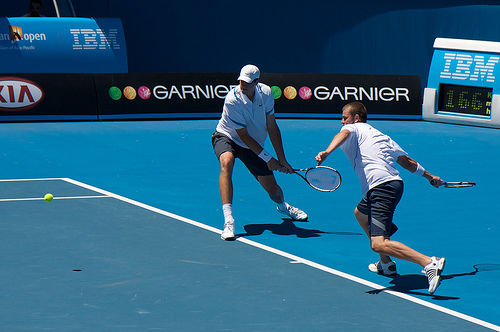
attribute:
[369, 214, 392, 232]
stripe — purple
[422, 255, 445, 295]
sneakers — white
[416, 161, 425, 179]
band — white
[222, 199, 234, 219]
socks — white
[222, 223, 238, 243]
sneakers — white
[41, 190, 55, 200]
tennis ball — green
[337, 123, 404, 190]
shirt — white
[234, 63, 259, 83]
hat — white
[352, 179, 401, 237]
shorts — blue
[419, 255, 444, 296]
shoe — white